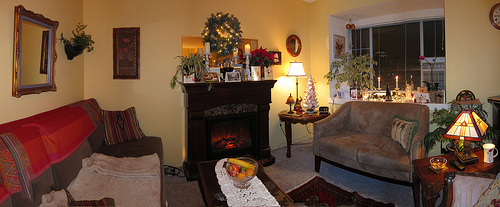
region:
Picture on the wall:
[103, 20, 151, 86]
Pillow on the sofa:
[386, 113, 418, 154]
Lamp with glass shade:
[443, 100, 488, 173]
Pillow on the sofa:
[93, 98, 148, 150]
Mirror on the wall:
[281, 20, 302, 54]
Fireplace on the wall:
[165, 75, 291, 180]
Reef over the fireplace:
[198, 3, 248, 58]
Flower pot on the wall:
[58, 13, 93, 65]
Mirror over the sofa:
[8, 3, 67, 104]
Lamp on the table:
[284, 57, 306, 115]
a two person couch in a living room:
[316, 94, 431, 204]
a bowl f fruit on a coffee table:
[223, 155, 258, 187]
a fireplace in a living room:
[181, 78, 277, 173]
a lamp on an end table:
[444, 108, 486, 166]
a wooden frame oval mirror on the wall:
[286, 35, 301, 56]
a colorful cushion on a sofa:
[99, 105, 147, 143]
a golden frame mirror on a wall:
[11, 5, 58, 97]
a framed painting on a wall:
[112, 27, 141, 81]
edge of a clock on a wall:
[488, 2, 499, 30]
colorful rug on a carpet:
[286, 177, 395, 204]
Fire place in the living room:
[174, 80, 280, 180]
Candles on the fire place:
[202, 40, 254, 79]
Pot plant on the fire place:
[168, 51, 207, 86]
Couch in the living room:
[0, 97, 163, 205]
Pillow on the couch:
[97, 102, 144, 142]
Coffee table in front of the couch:
[195, 153, 295, 204]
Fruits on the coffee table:
[224, 154, 258, 188]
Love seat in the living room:
[315, 100, 429, 202]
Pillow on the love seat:
[389, 117, 418, 151]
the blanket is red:
[0, 105, 97, 175]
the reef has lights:
[174, 5, 246, 62]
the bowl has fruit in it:
[211, 144, 280, 191]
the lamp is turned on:
[438, 102, 498, 167]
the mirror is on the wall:
[4, 13, 71, 110]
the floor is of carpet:
[275, 162, 312, 182]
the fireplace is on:
[173, 93, 266, 175]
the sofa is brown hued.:
[308, 89, 443, 173]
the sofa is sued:
[270, 108, 423, 168]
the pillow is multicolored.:
[53, 96, 148, 177]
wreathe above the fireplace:
[203, 14, 240, 55]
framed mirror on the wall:
[11, 5, 61, 98]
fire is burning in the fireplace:
[180, 78, 275, 174]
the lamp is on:
[445, 111, 485, 163]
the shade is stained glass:
[442, 109, 486, 139]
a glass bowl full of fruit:
[222, 155, 254, 185]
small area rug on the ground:
[285, 174, 388, 205]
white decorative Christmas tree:
[303, 78, 318, 112]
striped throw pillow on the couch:
[102, 106, 144, 146]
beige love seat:
[315, 100, 428, 187]